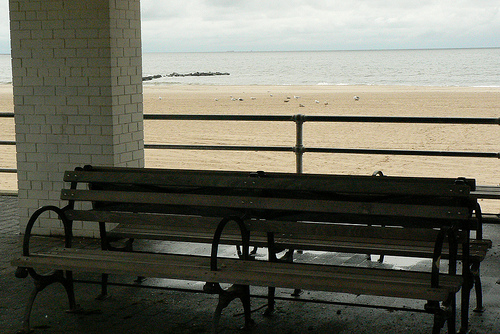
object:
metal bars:
[22, 205, 72, 254]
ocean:
[0, 48, 498, 86]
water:
[387, 256, 416, 268]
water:
[168, 52, 489, 87]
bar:
[197, 215, 257, 327]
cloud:
[143, 0, 498, 47]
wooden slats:
[58, 170, 472, 240]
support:
[12, 0, 124, 155]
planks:
[15, 247, 466, 302]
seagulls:
[214, 98, 219, 101]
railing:
[137, 112, 499, 195]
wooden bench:
[8, 164, 491, 333]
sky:
[139, 0, 494, 42]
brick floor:
[2, 221, 499, 332]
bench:
[11, 164, 491, 334]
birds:
[250, 97, 256, 101]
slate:
[58, 188, 475, 223]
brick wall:
[9, 0, 146, 238]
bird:
[314, 100, 321, 104]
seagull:
[354, 96, 360, 101]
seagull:
[324, 100, 329, 106]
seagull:
[284, 100, 290, 103]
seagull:
[298, 103, 305, 107]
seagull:
[293, 95, 300, 99]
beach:
[0, 47, 498, 215]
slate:
[58, 209, 467, 246]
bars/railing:
[139, 109, 500, 177]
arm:
[405, 186, 483, 331]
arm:
[3, 183, 86, 296]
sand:
[0, 75, 500, 204]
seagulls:
[158, 96, 163, 101]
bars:
[144, 113, 499, 125]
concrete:
[27, 273, 429, 331]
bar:
[418, 225, 478, 332]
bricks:
[6, 3, 152, 238]